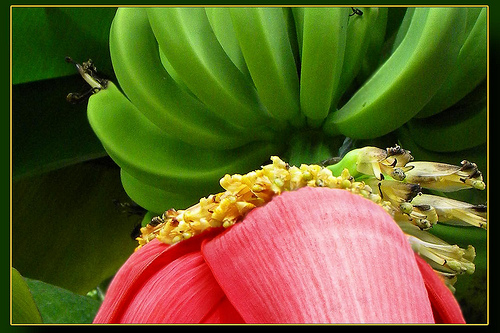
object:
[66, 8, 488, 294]
bananas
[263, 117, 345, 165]
green stem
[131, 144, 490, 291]
flower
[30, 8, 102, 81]
shadow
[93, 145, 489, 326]
plant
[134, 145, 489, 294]
petal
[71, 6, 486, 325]
plantains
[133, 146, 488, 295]
yellow top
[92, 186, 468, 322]
leaves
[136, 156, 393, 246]
seeds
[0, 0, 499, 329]
photo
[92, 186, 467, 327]
red petals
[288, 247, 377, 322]
lines